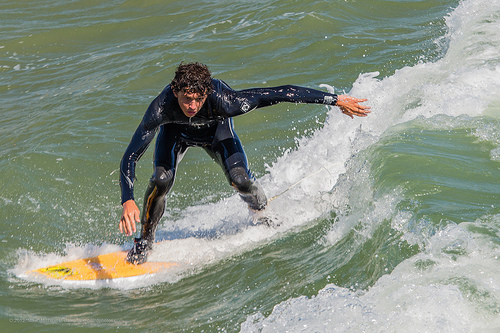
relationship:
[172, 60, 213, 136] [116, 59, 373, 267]
head of man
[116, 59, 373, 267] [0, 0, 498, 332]
man surfing in ocean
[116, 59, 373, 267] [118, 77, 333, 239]
man in black wetsuit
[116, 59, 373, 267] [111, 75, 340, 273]
man in wetsuit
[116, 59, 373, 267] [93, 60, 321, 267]
man in wetsuit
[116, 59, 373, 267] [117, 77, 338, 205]
man in black wetsuit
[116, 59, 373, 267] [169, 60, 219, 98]
man with hair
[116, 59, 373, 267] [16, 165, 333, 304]
man on surfboard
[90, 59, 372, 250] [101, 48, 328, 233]
man wearing wetsuit.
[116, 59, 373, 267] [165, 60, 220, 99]
man has hair